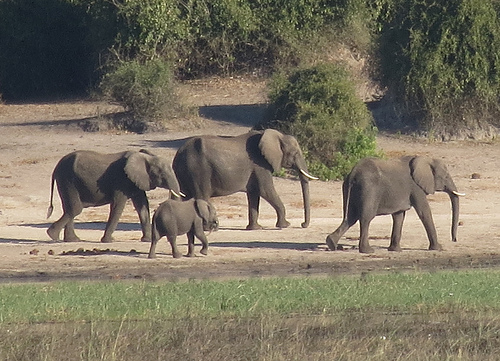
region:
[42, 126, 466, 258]
grey elephants in herd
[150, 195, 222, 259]
baby elephant in herd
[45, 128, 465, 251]
grey elephants have ivory white tusks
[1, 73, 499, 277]
light brown dirt under elephants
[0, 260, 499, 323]
green grass beside elephants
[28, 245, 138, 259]
large pile beside elephants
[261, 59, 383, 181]
lone large bush by elephants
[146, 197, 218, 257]
The elephant in the frame is a baby.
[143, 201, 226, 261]
The baby elephant is walking.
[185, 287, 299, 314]
The grass in the forefront in green.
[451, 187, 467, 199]
The elephants tusk is white.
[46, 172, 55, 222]
The elephants tail is long.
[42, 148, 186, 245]
The elephant is gray in color.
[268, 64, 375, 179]
The bush in the background is green in color.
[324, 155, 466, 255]
The elephant is walking.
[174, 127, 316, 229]
The elephant is very large.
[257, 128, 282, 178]
The elephants ear is large.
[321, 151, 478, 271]
elephant in the sand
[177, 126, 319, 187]
elephant in the sand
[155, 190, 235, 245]
elephant in the sand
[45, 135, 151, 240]
elephant in the sand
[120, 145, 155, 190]
ear on a elephant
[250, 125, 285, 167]
ear on an elephant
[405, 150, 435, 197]
ear on elephant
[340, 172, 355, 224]
tail of an elephant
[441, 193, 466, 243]
trunk of an elephant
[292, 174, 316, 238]
trunk on an elephant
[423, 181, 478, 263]
trunk of the elephant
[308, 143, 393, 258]
back part of elephant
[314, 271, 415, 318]
green grass on ground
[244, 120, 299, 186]
ear of the elephant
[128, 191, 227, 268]
baby elephant next to adults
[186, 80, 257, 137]
shadow of the tree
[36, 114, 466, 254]
four elephants walking together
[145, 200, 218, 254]
baby elephant in the group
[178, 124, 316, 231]
largest elephant in the group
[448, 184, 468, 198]
tusk of the lead elephant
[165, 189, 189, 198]
white tusks of the last elephant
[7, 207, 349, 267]
shadows of the elephants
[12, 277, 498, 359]
grass growing in the foreground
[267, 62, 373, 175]
green bush behind the elephants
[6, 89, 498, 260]
dirt path elephants are walking on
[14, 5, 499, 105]
trees behind the path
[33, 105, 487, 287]
the elephants are walking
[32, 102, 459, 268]
the elephants are walking